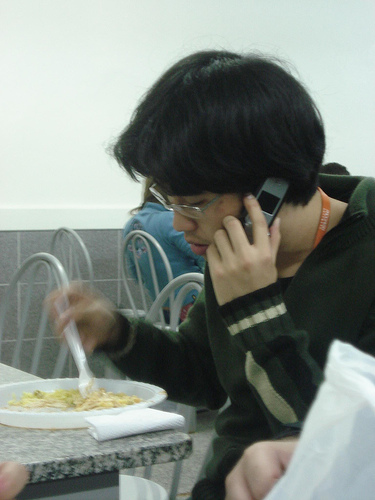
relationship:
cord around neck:
[260, 141, 366, 317] [266, 184, 345, 256]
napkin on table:
[71, 366, 214, 451] [3, 363, 186, 487]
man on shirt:
[100, 37, 352, 402] [116, 174, 375, 478]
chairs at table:
[0, 200, 213, 368] [3, 363, 186, 487]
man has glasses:
[100, 37, 352, 402] [121, 172, 222, 238]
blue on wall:
[10, 64, 80, 176] [8, 4, 136, 202]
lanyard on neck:
[295, 189, 335, 285] [260, 141, 366, 317]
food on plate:
[21, 362, 161, 418] [2, 347, 177, 446]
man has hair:
[100, 37, 352, 402] [154, 54, 299, 153]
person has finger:
[100, 37, 352, 402] [187, 205, 281, 306]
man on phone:
[100, 37, 352, 402] [205, 134, 312, 294]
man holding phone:
[100, 37, 352, 402] [205, 134, 312, 294]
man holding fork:
[100, 37, 352, 402] [31, 212, 156, 419]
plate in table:
[2, 347, 177, 446] [3, 363, 186, 487]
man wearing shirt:
[100, 37, 352, 402] [178, 176, 371, 377]